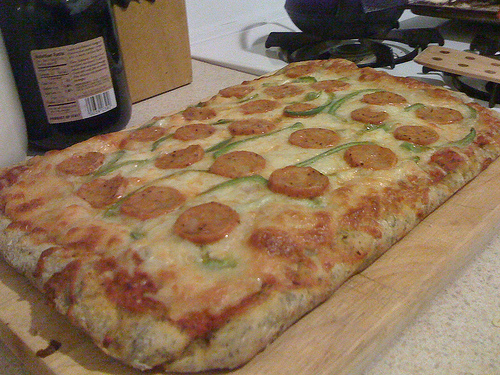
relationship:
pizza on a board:
[1, 57, 499, 375] [1, 157, 500, 373]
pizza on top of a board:
[1, 57, 499, 375] [1, 157, 500, 373]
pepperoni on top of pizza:
[174, 202, 241, 246] [1, 57, 499, 375]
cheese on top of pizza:
[3, 59, 500, 323] [1, 57, 499, 375]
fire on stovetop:
[323, 38, 378, 60] [184, 1, 499, 113]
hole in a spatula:
[440, 49, 451, 55] [413, 45, 500, 84]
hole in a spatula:
[431, 56, 444, 62] [413, 45, 500, 84]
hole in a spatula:
[464, 55, 475, 61] [413, 45, 500, 84]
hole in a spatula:
[457, 62, 470, 68] [413, 45, 500, 84]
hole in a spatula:
[491, 61, 500, 67] [413, 45, 500, 84]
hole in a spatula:
[484, 68, 497, 75] [413, 45, 500, 84]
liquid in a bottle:
[1, 1, 131, 153] [1, 1, 131, 153]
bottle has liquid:
[1, 1, 131, 153] [1, 1, 131, 153]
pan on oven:
[284, 1, 409, 38] [184, 1, 499, 113]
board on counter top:
[1, 157, 500, 373] [0, 57, 499, 374]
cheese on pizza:
[3, 59, 500, 323] [1, 57, 499, 375]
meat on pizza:
[56, 63, 463, 244] [1, 57, 499, 375]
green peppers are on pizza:
[91, 75, 478, 269] [1, 57, 499, 375]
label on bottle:
[28, 35, 117, 125] [1, 1, 131, 153]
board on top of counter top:
[1, 157, 500, 373] [0, 57, 499, 374]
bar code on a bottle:
[83, 89, 114, 118] [1, 1, 131, 153]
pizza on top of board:
[1, 57, 499, 375] [1, 157, 500, 373]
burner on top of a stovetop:
[265, 25, 444, 73] [184, 1, 499, 113]